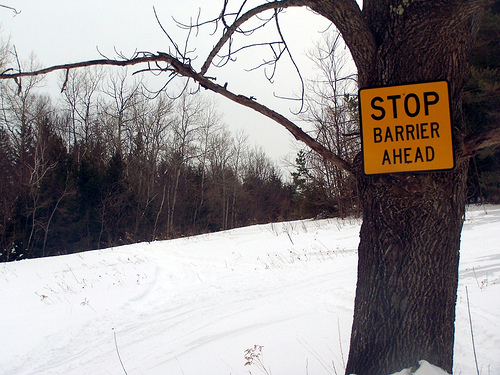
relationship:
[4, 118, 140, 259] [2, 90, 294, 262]
evergreens hiding among trees